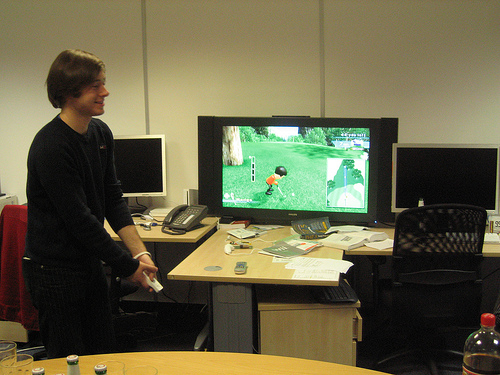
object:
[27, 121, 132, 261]
shirt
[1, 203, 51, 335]
jacket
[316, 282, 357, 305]
keyboard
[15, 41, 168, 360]
boy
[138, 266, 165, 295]
controller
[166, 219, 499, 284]
table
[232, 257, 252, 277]
cell phone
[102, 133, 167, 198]
monitor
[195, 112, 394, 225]
tv set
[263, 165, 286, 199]
wii golfer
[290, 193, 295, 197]
ball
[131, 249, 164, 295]
wii remote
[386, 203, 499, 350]
computer chair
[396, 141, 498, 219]
monitor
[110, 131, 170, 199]
computer monitor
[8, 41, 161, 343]
man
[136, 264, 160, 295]
controller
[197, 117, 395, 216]
tv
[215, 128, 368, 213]
game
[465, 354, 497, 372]
soda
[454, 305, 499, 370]
bottle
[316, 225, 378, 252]
book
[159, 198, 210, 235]
telephone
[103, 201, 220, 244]
table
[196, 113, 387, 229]
tv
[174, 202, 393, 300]
table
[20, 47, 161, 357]
man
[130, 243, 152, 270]
wrist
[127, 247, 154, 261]
band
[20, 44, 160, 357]
person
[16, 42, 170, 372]
man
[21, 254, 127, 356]
pants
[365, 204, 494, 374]
chair